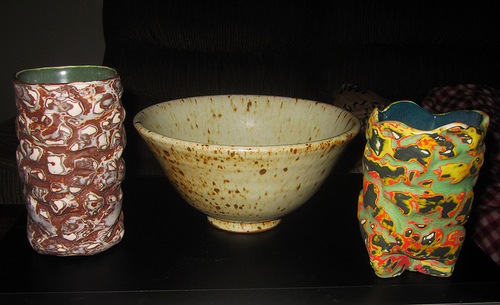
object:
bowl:
[132, 95, 359, 232]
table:
[0, 183, 495, 299]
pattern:
[10, 62, 130, 255]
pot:
[357, 100, 490, 275]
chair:
[393, 72, 452, 94]